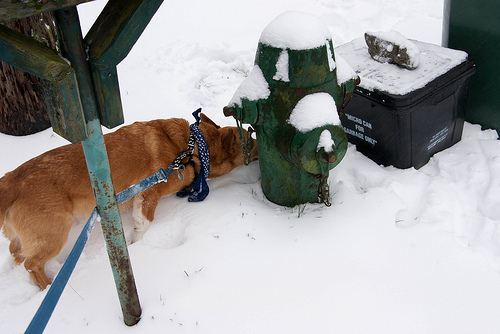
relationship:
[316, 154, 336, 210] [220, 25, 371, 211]
chain on hydrant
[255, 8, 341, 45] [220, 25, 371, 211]
snow on hydrant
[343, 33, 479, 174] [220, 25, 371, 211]
box near hydrant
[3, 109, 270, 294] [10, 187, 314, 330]
dog in snow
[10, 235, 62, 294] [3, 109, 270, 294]
legs of dog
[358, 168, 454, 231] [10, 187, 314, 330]
footprints in snow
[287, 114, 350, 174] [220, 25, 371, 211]
attachment on hydrant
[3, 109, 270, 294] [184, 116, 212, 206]
dog on collar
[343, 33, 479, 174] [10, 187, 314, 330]
bin in snow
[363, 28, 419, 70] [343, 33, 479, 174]
rock on bin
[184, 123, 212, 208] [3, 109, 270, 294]
collar on dog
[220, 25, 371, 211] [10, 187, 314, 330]
hydrant in snow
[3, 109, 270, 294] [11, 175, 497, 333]
dog in snow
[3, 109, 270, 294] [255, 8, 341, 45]
dog in snow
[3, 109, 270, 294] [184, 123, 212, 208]
dog with collar